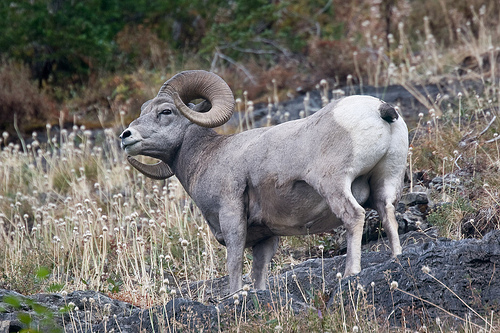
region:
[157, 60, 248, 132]
large horn on a ram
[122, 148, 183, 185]
large horn on a ram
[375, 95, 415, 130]
small tail on a ram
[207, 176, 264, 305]
front leg of a ram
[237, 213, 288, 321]
front leg of a ram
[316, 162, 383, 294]
rear leg on a ram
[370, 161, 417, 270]
rear leg on a ram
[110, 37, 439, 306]
ram standing in a field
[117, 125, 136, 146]
nose of a ram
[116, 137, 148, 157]
mouth of a ram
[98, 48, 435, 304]
ram on a hlilside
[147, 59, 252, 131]
curled ram's horn on his head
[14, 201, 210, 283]
small buds on head of plants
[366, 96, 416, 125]
black tail on rear of ram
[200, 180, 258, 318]
front left leg of ram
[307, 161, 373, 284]
left rear leg of ram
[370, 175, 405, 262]
right rear leg of ram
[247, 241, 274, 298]
front right leg of ram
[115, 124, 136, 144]
nostril of a ram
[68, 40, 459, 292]
a ram looking to the left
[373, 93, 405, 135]
short black stubby tail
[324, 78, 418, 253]
white rear and back of legs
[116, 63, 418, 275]
a male Big Horn Sheep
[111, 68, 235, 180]
longer curvier horns show this is a ram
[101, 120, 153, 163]
lighter area at tip of muzzle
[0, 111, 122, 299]
sparse dried grass gone to seed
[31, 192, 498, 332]
rough rocky terrain for climbing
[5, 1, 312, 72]
green brush on hill side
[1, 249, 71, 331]
green weed in the foreground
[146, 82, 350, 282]
a mostly grey coat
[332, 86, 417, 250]
white rear area and back of legs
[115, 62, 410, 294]
Large Male Big Horned Sheep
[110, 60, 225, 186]
Ram with longer and curvier horns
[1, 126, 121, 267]
dried grass gone to seed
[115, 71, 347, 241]
most of body is grey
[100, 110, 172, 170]
the tip on muzzle is white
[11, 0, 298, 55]
green still shows on hill side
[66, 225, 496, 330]
a rocky terrain to climb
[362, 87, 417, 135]
a short stubby tail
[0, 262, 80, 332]
a green wees in the foreground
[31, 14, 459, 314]
bighorn sheep on a rocky slope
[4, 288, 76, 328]
green moss and lichen on a gray rock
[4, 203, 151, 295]
dried wild plants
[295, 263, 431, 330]
dark gray rock on a hillside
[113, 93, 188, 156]
face of a bighorn sheep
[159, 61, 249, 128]
bighorn sheep's left horn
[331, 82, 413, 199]
bighorn sheep's white rump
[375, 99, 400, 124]
tail of a bighorn sheep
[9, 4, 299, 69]
green shrubs on a hillside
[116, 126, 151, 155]
bighorn sheep's white muzzle